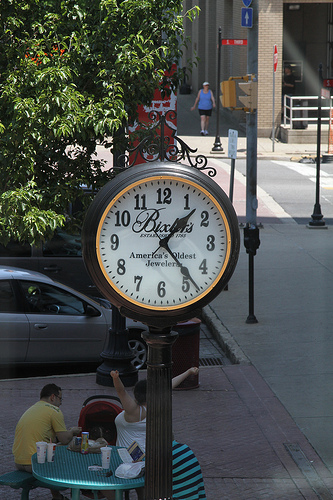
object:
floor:
[0, 94, 333, 496]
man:
[13, 383, 82, 473]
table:
[32, 443, 145, 498]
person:
[172, 442, 205, 499]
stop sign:
[273, 44, 278, 72]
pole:
[272, 45, 274, 153]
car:
[0, 263, 150, 372]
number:
[157, 187, 172, 204]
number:
[207, 235, 215, 251]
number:
[182, 276, 189, 292]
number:
[134, 276, 143, 292]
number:
[110, 234, 119, 250]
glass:
[99, 178, 224, 308]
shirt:
[11, 400, 67, 464]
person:
[190, 82, 216, 136]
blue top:
[198, 89, 212, 110]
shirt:
[171, 443, 205, 499]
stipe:
[171, 443, 183, 451]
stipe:
[171, 468, 202, 485]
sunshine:
[177, 136, 333, 221]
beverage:
[100, 446, 111, 468]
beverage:
[47, 443, 55, 462]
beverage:
[36, 441, 47, 463]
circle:
[95, 176, 231, 314]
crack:
[203, 475, 290, 478]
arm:
[114, 378, 135, 412]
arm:
[172, 369, 191, 389]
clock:
[82, 164, 240, 318]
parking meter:
[243, 223, 260, 323]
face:
[95, 176, 227, 308]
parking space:
[0, 319, 233, 381]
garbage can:
[171, 318, 199, 389]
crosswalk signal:
[220, 80, 236, 108]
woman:
[110, 370, 146, 454]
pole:
[145, 326, 173, 499]